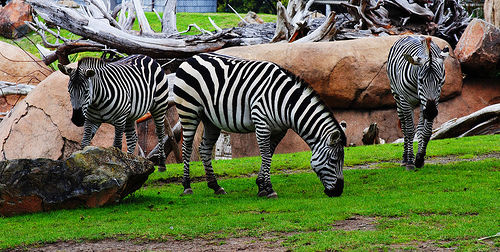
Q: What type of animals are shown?
A: Zebras.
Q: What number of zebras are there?
A: 3.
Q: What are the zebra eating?
A: Grass.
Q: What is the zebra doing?
A: Eating grass.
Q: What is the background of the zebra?
A: Wood.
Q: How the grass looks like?
A: Fresh.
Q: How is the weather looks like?
A: Good.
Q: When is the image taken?
A: Zebra is eating grass.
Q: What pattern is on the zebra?
A: Stripes.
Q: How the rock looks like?
A: Big gray.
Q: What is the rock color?
A: Gray.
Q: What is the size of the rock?
A: Big gray rock.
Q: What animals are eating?
A: Zebra.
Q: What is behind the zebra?
A: Big rock.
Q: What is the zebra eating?
A: Grass.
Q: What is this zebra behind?
A: Rocks.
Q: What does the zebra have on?
A: Flu with strips.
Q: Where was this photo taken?
A: In the wild.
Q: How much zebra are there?
A: Three.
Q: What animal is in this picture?
A: Zebra.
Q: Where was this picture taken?
A: Zoo.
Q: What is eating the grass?
A: Zebra.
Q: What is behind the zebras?
A: Rocks.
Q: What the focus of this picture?
A: Zebra.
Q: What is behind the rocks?
A: Logs.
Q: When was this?
A: Daytime.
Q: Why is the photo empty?
A: There is no one.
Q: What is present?
A: Animals.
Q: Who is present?
A: Nobody.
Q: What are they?
A: Zebras.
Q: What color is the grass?
A: Green.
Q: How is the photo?
A: Clear.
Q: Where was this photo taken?
A: At a zoo.